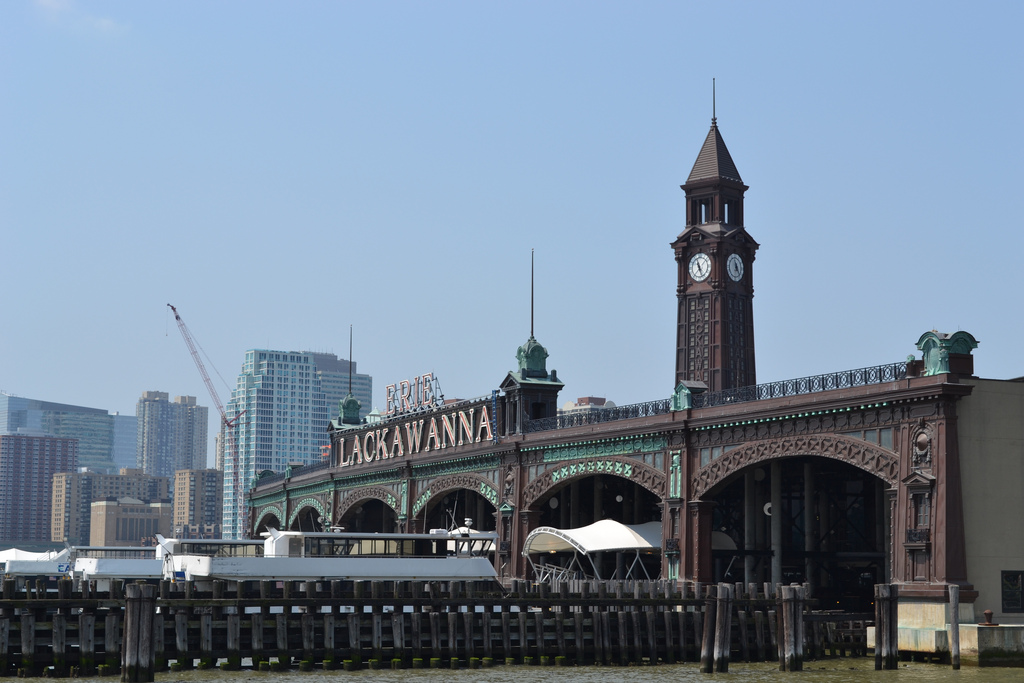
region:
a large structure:
[232, 381, 997, 634]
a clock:
[690, 256, 704, 282]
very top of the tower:
[702, 59, 721, 140]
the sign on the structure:
[327, 365, 492, 463]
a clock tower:
[671, 42, 766, 403]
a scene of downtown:
[28, 35, 1016, 671]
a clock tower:
[637, 53, 794, 447]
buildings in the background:
[2, 297, 448, 574]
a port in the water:
[18, 445, 1018, 680]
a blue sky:
[8, 6, 1015, 463]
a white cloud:
[5, 0, 202, 95]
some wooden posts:
[3, 518, 867, 680]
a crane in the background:
[138, 265, 260, 566]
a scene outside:
[28, 48, 1022, 524]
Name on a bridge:
[327, 371, 498, 470]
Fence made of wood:
[10, 570, 823, 662]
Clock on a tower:
[681, 248, 714, 283]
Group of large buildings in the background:
[4, 365, 227, 546]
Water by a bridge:
[197, 653, 965, 680]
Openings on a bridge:
[668, 415, 900, 615]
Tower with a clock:
[662, 90, 770, 400]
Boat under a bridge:
[525, 508, 751, 589]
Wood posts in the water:
[866, 567, 905, 678]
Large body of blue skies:
[419, 62, 607, 189]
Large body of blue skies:
[815, 53, 983, 254]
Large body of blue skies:
[85, 75, 368, 227]